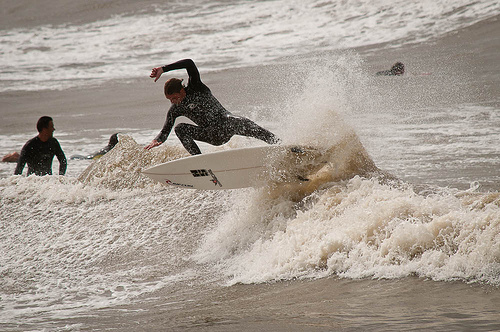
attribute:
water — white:
[1, 2, 498, 93]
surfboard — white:
[140, 145, 305, 190]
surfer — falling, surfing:
[141, 59, 285, 156]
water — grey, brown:
[1, 1, 499, 331]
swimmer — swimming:
[374, 62, 407, 78]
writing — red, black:
[207, 169, 223, 190]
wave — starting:
[206, 1, 499, 72]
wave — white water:
[1, 140, 499, 288]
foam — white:
[187, 174, 499, 286]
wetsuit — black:
[153, 58, 279, 155]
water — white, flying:
[268, 49, 396, 142]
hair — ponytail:
[164, 78, 186, 96]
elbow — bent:
[182, 58, 198, 75]